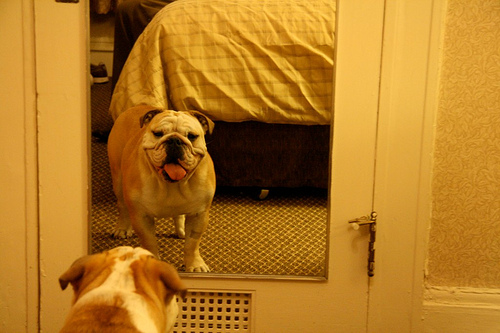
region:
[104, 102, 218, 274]
A reflection of a dog.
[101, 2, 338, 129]
A bed with a comforter.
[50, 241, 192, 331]
Dog looking into a mirror.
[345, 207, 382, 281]
A door hinge with stopper.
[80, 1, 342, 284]
A mirror reflecting a bedroom.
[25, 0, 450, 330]
A door with a mirror.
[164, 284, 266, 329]
A vent in a door.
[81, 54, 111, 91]
A pair of shoes.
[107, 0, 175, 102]
A person's knee.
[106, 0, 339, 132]
A checkered comforter.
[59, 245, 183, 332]
dog facing the mirror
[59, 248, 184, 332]
brown and white dog's back of head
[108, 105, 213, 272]
Dog's reflection in the mirror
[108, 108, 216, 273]
Chubby reflection of dog in the mirror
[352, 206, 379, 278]
Hinges on the door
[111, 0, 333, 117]
yellow bed spread on bed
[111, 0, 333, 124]
Yellow spread with light lines through them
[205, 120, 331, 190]
Dark brown wooden bed bottom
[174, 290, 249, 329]
Ventilator on closet door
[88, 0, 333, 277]
Mirror on closet door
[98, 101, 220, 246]
a dog's reflection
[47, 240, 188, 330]
a dog's head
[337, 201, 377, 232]
a mounted doorstop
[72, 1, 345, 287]
a mirror mounted on a door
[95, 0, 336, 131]
a bed white striped comforter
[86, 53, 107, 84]
a pair of shoes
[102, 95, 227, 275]
a bulldog with it's tongue hanging out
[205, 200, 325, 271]
reflection of patterned carpeting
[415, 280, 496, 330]
white wall moulding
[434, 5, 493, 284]
patterned wallpaper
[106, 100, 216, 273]
dog's reflection in mirror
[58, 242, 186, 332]
dog standing in front of mirror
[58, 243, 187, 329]
brown and white dog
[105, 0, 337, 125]
blanket with a square pattern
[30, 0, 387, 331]
mirror on door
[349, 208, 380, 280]
hinge of door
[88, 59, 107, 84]
shoe reflected in mirror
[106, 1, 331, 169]
bed reflected in mirror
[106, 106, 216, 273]
dog's tongue is hanging out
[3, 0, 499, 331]
white door and doorframe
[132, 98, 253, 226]
smiling dog in mirror.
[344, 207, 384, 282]
hinge attached to the door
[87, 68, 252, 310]
bull dog in the mirror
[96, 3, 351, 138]
checkered bed spread on bed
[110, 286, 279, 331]
grate attached to the door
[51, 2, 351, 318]
mirror attached to the door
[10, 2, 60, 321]
crease next to the door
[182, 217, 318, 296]
checkered shaped rug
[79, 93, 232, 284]
large brown and white dog in mirror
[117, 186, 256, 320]
dog paws on carpet